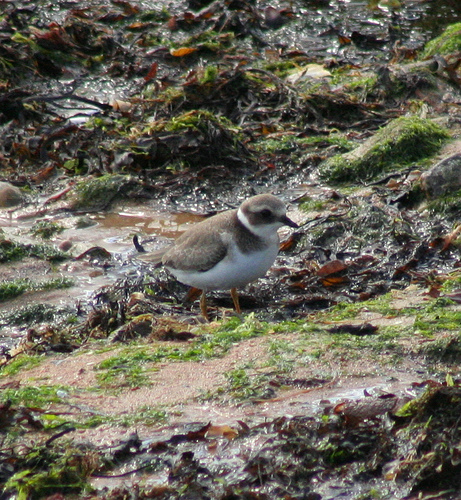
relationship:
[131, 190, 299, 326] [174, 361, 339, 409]
bird on ground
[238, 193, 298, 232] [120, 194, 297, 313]
head of bird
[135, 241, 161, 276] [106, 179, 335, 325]
tail of bird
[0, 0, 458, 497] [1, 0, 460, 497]
water covered ground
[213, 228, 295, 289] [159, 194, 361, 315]
chest of bird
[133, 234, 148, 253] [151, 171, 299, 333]
tail of bird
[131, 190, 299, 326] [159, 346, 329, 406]
bird standing on ground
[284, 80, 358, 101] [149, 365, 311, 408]
leaves on ground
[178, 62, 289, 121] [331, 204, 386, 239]
grass on murky area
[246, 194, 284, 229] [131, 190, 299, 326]
head of bird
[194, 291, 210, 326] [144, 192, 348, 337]
leg of bird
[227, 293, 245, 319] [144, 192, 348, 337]
leg of bird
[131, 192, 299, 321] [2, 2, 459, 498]
bird stand on a muddy surface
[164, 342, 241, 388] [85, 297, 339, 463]
space on ground